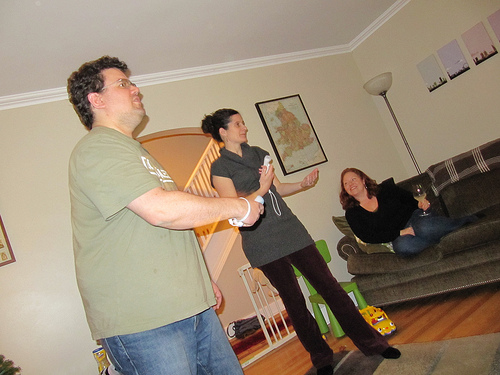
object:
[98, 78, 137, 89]
specs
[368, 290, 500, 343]
tiles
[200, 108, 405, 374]
person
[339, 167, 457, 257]
person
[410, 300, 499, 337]
ground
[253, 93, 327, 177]
frame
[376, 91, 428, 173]
metal pole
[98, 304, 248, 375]
jean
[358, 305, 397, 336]
toy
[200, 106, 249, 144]
woman's head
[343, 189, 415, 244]
shirt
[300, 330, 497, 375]
rug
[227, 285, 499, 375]
floor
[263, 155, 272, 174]
controllers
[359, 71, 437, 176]
lamp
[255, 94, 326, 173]
picture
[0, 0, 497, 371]
wall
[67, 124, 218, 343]
green color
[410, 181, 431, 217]
glass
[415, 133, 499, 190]
blanket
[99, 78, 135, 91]
glasses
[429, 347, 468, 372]
dirt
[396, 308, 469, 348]
snow.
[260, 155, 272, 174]
devices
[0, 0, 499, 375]
image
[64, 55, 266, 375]
man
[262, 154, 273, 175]
games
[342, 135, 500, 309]
couch